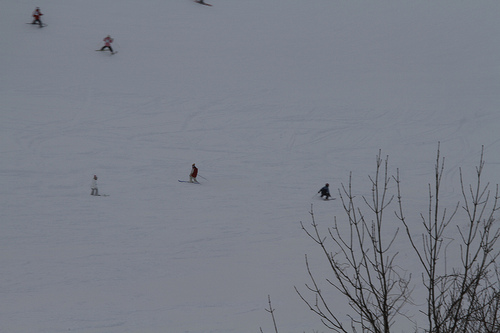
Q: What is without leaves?
A: The brown tree.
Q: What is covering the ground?
A: Snow.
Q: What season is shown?
A: Winter.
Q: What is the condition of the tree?
A: Bare.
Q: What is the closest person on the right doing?
A: Skiing.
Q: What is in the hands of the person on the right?
A: Ski poles.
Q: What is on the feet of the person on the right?
A: Skis.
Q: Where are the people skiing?
A: On a hill.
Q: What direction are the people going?
A: Downhill.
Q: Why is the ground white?
A: It's covered in snow.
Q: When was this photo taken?
A: During the daytime.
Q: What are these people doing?
A: Skiing.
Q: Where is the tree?
A: Bottom Right.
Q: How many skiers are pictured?
A: Five.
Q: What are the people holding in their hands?
A: Ski Poles.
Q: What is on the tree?
A: Nothing.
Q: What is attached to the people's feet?
A: Skis.